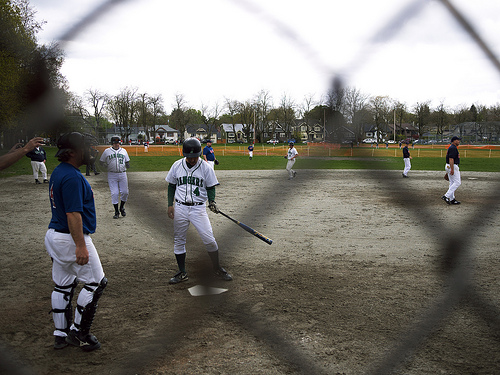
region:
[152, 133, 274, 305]
player up to bat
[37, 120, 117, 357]
player wearing catchers equipment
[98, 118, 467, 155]
houses behind baseball field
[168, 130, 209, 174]
baseball wearing safety helmet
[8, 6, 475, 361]
image taken through chain link fence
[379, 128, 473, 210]
players walking to outfield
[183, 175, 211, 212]
player wearing the number four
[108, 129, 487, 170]
fence around the baseball field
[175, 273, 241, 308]
batter standing at home plate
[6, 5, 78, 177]
large tree beside field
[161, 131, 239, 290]
a man in a white jersey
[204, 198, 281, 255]
a baseball bat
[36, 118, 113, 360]
a catcher in a blue jersey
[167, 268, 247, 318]
a white home plate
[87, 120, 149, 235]
the runner on third base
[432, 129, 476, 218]
a baseball pitcher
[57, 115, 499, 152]
many houses in the background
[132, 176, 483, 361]
brown sandy dirt on a baseball field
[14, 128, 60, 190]
the third base coach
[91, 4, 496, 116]
a partially cloudy sky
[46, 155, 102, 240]
the catcher is wearing a blue shirt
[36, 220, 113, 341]
the catcher is wearing white pants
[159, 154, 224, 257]
the batter is wearing a uniform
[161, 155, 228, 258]
the batter's uniform is white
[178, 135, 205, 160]
the batter is wearing a helmet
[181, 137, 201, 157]
the helmet is black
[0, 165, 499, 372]
the ground is dirt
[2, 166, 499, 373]
the dirt is brown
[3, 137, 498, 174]
the grass is green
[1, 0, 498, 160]
the sky is bright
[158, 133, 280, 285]
A BASEBALL PLAYER HOLDING A BAT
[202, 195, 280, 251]
A WOODEN BASEBALL BAT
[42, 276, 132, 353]
A PAIR OF SHINE GUARDS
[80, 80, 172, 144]
TREES IN THE DISTANCE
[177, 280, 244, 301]
A WHITE BASEBALL BASE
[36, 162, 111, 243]
A BLUE JERSEY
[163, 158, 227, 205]
A WHITE BASEBALL JERSEY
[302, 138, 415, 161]
A METAL FENCE IN THE DISTANCE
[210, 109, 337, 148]
HOUSES IN THE DISTANCE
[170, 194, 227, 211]
A MANS BELT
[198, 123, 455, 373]
Small opening in the chain link fence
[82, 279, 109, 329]
Wearing black guard on leg that protects knee to ankle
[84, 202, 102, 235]
Man in blue shirt has a beer belly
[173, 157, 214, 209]
Batter is number four on his team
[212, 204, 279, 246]
Baseball bat is black, beige, and blue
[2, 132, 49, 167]
Somebody's right hand and arm are reaching for catcher's head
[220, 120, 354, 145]
Several two story houses are across from baseball field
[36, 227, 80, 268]
Catcher's white pants are very baggy in the butt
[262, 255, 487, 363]
Ground appears moist, as if it rained recently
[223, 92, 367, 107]
Several tall trees around houses that lost their leaves